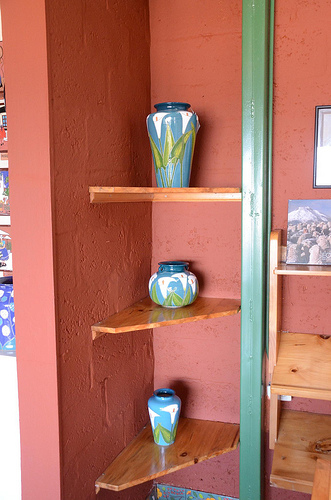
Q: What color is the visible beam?
A: Green.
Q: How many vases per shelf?
A: 1.